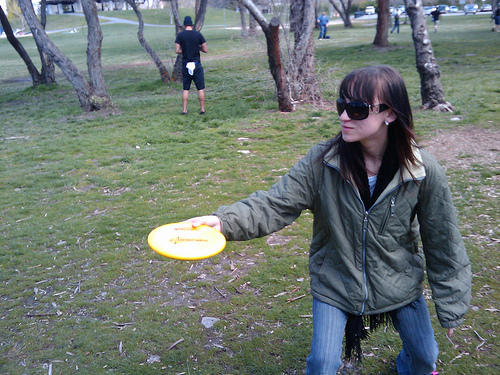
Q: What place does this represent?
A: It represents the park.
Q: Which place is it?
A: It is a park.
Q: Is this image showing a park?
A: Yes, it is showing a park.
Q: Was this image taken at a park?
A: Yes, it was taken in a park.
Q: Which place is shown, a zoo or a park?
A: It is a park.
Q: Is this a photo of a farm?
A: No, the picture is showing a park.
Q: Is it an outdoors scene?
A: Yes, it is outdoors.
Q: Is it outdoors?
A: Yes, it is outdoors.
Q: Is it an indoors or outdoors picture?
A: It is outdoors.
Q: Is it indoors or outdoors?
A: It is outdoors.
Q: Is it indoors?
A: No, it is outdoors.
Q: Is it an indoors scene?
A: No, it is outdoors.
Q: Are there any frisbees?
A: Yes, there is a frisbee.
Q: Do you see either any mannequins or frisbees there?
A: Yes, there is a frisbee.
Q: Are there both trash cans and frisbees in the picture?
A: No, there is a frisbee but no trash cans.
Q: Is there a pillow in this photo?
A: No, there are no pillows.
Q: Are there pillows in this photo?
A: No, there are no pillows.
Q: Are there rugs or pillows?
A: No, there are no pillows or rugs.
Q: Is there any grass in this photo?
A: Yes, there is grass.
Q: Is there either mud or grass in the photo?
A: Yes, there is grass.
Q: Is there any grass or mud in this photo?
A: Yes, there is grass.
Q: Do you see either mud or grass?
A: Yes, there is grass.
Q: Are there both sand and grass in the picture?
A: No, there is grass but no sand.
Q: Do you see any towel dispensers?
A: No, there are no towel dispensers.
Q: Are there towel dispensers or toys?
A: No, there are no towel dispensers or toys.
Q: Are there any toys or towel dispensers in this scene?
A: No, there are no towel dispensers or toys.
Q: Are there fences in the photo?
A: No, there are no fences.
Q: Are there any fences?
A: No, there are no fences.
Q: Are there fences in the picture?
A: No, there are no fences.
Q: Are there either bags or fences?
A: No, there are no fences or bags.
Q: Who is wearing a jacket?
A: The people are wearing a jacket.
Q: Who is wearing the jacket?
A: The people are wearing a jacket.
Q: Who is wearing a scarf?
A: The people are wearing a scarf.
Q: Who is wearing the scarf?
A: The people are wearing a scarf.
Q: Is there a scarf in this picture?
A: Yes, there is a scarf.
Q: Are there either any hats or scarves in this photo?
A: Yes, there is a scarf.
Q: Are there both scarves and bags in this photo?
A: No, there is a scarf but no bags.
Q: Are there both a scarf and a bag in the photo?
A: No, there is a scarf but no bags.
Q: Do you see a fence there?
A: No, there are no fences.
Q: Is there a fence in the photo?
A: No, there are no fences.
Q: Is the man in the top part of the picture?
A: Yes, the man is in the top of the image.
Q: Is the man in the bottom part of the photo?
A: No, the man is in the top of the image.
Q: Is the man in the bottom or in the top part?
A: The man is in the top of the image.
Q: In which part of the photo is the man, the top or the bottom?
A: The man is in the top of the image.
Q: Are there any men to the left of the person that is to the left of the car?
A: Yes, there is a man to the left of the person.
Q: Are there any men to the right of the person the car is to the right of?
A: No, the man is to the left of the person.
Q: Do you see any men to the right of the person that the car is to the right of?
A: No, the man is to the left of the person.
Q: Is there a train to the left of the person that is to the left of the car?
A: No, there is a man to the left of the person.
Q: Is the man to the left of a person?
A: Yes, the man is to the left of a person.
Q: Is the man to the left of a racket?
A: No, the man is to the left of a person.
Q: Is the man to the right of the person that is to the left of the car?
A: No, the man is to the left of the person.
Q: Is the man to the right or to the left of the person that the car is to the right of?
A: The man is to the left of the person.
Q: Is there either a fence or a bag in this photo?
A: No, there are no fences or bags.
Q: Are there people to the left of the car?
A: Yes, there is a person to the left of the car.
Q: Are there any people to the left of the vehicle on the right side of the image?
A: Yes, there is a person to the left of the car.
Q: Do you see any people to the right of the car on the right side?
A: No, the person is to the left of the car.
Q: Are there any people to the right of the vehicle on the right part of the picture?
A: No, the person is to the left of the car.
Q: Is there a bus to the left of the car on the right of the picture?
A: No, there is a person to the left of the car.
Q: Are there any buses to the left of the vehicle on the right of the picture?
A: No, there is a person to the left of the car.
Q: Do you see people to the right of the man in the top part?
A: Yes, there is a person to the right of the man.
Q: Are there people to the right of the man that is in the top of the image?
A: Yes, there is a person to the right of the man.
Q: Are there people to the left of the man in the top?
A: No, the person is to the right of the man.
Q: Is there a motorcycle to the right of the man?
A: No, there is a person to the right of the man.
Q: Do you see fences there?
A: No, there are no fences.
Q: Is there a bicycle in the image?
A: No, there are no bicycles.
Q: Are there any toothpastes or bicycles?
A: No, there are no bicycles or toothpastes.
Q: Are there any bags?
A: No, there are no bags.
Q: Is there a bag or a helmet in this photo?
A: No, there are no bags or helmets.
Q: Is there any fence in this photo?
A: No, there are no fences.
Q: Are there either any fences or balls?
A: No, there are no fences or balls.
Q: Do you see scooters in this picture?
A: No, there are no scooters.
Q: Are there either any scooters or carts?
A: No, there are no scooters or carts.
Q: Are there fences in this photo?
A: No, there are no fences.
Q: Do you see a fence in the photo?
A: No, there are no fences.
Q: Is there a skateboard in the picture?
A: No, there are no skateboards.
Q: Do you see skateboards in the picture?
A: No, there are no skateboards.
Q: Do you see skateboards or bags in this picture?
A: No, there are no skateboards or bags.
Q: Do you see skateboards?
A: No, there are no skateboards.